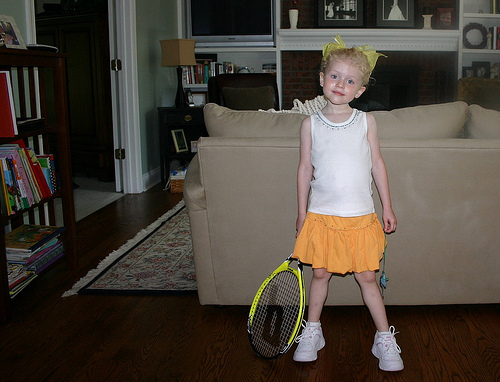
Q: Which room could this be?
A: It is a living room.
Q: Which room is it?
A: It is a living room.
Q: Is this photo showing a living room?
A: Yes, it is showing a living room.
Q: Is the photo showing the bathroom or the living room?
A: It is showing the living room.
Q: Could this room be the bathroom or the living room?
A: It is the living room.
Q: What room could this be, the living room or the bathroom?
A: It is the living room.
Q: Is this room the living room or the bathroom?
A: It is the living room.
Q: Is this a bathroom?
A: No, it is a living room.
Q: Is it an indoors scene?
A: Yes, it is indoors.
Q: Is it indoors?
A: Yes, it is indoors.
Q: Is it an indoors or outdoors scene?
A: It is indoors.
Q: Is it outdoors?
A: No, it is indoors.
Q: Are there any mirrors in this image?
A: No, there are no mirrors.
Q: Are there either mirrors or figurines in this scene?
A: No, there are no mirrors or figurines.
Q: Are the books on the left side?
A: Yes, the books are on the left of the image.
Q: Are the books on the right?
A: No, the books are on the left of the image.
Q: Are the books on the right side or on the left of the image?
A: The books are on the left of the image.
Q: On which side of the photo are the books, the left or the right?
A: The books are on the left of the image.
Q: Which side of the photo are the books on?
A: The books are on the left of the image.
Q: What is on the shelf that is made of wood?
A: The books are on the shelf.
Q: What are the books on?
A: The books are on the shelf.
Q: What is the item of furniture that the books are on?
A: The piece of furniture is a shelf.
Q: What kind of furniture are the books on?
A: The books are on the shelf.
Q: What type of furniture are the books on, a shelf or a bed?
A: The books are on a shelf.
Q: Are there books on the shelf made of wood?
A: Yes, there are books on the shelf.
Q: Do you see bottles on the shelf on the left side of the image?
A: No, there are books on the shelf.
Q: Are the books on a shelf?
A: Yes, the books are on a shelf.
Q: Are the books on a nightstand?
A: No, the books are on a shelf.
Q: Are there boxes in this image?
A: No, there are no boxes.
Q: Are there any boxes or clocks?
A: No, there are no boxes or clocks.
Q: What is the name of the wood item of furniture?
A: The piece of furniture is a shelf.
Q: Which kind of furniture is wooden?
A: The furniture is a shelf.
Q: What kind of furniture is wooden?
A: The furniture is a shelf.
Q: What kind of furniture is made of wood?
A: The furniture is a shelf.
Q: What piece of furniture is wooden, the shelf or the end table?
A: The shelf is wooden.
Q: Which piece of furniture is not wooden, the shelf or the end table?
A: The end table is not wooden.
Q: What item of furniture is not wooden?
A: The piece of furniture is an end table.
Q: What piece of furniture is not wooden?
A: The piece of furniture is an end table.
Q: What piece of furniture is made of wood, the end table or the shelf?
A: The shelf is made of wood.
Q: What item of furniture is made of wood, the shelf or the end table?
A: The shelf is made of wood.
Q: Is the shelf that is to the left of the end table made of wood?
A: Yes, the shelf is made of wood.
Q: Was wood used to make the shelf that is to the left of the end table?
A: Yes, the shelf is made of wood.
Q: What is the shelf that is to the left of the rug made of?
A: The shelf is made of wood.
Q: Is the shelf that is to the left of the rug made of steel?
A: No, the shelf is made of wood.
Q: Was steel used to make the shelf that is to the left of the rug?
A: No, the shelf is made of wood.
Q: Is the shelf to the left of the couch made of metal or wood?
A: The shelf is made of wood.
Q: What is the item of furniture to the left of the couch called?
A: The piece of furniture is a shelf.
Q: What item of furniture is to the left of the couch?
A: The piece of furniture is a shelf.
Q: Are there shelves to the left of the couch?
A: Yes, there is a shelf to the left of the couch.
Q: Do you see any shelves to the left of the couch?
A: Yes, there is a shelf to the left of the couch.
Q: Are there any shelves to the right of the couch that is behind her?
A: No, the shelf is to the left of the couch.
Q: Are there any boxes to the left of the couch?
A: No, there is a shelf to the left of the couch.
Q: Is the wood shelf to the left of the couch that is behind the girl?
A: Yes, the shelf is to the left of the couch.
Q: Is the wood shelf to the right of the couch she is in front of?
A: No, the shelf is to the left of the couch.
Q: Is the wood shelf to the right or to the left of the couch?
A: The shelf is to the left of the couch.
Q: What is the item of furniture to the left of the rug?
A: The piece of furniture is a shelf.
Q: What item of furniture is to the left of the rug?
A: The piece of furniture is a shelf.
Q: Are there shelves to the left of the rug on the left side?
A: Yes, there is a shelf to the left of the rug.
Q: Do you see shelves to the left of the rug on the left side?
A: Yes, there is a shelf to the left of the rug.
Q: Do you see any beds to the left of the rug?
A: No, there is a shelf to the left of the rug.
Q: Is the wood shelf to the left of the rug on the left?
A: Yes, the shelf is to the left of the rug.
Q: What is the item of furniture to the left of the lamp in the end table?
A: The piece of furniture is a shelf.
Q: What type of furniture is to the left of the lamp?
A: The piece of furniture is a shelf.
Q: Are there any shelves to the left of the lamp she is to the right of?
A: Yes, there is a shelf to the left of the lamp.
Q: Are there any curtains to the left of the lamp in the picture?
A: No, there is a shelf to the left of the lamp.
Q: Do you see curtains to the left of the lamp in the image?
A: No, there is a shelf to the left of the lamp.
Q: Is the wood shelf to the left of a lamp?
A: Yes, the shelf is to the left of a lamp.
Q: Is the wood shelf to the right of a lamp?
A: No, the shelf is to the left of a lamp.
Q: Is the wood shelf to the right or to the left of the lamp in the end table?
A: The shelf is to the left of the lamp.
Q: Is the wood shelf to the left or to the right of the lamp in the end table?
A: The shelf is to the left of the lamp.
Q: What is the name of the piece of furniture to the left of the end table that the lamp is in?
A: The piece of furniture is a shelf.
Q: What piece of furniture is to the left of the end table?
A: The piece of furniture is a shelf.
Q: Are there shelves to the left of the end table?
A: Yes, there is a shelf to the left of the end table.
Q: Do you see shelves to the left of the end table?
A: Yes, there is a shelf to the left of the end table.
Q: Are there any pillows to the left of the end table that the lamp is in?
A: No, there is a shelf to the left of the end table.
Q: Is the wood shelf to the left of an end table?
A: Yes, the shelf is to the left of an end table.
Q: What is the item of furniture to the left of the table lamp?
A: The piece of furniture is a shelf.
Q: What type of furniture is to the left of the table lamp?
A: The piece of furniture is a shelf.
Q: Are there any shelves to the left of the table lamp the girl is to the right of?
A: Yes, there is a shelf to the left of the table lamp.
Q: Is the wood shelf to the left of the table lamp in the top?
A: Yes, the shelf is to the left of the table lamp.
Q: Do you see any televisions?
A: Yes, there is a television.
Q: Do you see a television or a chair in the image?
A: Yes, there is a television.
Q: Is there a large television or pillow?
A: Yes, there is a large television.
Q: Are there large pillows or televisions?
A: Yes, there is a large television.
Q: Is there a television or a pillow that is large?
A: Yes, the television is large.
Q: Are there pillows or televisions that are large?
A: Yes, the television is large.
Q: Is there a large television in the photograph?
A: Yes, there is a large television.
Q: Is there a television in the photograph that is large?
A: Yes, there is a television that is large.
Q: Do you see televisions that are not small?
A: Yes, there is a large television.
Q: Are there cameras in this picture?
A: No, there are no cameras.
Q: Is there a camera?
A: No, there are no cameras.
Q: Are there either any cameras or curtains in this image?
A: No, there are no cameras or curtains.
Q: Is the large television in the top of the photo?
A: Yes, the TV is in the top of the image.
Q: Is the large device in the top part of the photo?
A: Yes, the TV is in the top of the image.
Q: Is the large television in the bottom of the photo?
A: No, the TV is in the top of the image.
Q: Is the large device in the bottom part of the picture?
A: No, the TV is in the top of the image.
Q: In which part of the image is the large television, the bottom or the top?
A: The TV is in the top of the image.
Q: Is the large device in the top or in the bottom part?
A: The TV is in the top of the image.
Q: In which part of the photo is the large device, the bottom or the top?
A: The TV is in the top of the image.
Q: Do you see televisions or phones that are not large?
A: No, there is a television but it is large.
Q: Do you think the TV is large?
A: Yes, the TV is large.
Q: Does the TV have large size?
A: Yes, the TV is large.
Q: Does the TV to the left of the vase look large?
A: Yes, the television is large.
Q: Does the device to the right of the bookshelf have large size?
A: Yes, the television is large.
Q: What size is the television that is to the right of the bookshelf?
A: The television is large.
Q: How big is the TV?
A: The TV is large.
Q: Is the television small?
A: No, the television is large.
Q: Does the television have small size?
A: No, the television is large.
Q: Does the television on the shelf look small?
A: No, the television is large.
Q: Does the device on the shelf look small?
A: No, the television is large.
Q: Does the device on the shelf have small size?
A: No, the television is large.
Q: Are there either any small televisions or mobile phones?
A: No, there is a television but it is large.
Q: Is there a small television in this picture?
A: No, there is a television but it is large.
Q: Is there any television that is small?
A: No, there is a television but it is large.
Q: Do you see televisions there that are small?
A: No, there is a television but it is large.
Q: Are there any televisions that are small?
A: No, there is a television but it is large.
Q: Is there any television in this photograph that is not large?
A: No, there is a television but it is large.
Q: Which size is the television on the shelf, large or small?
A: The television is large.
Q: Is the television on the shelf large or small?
A: The television is large.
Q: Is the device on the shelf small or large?
A: The television is large.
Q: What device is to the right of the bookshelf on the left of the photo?
A: The device is a television.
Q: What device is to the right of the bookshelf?
A: The device is a television.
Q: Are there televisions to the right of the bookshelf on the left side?
A: Yes, there is a television to the right of the bookshelf.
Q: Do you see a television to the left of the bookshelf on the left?
A: No, the television is to the right of the bookshelf.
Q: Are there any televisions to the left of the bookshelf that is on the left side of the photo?
A: No, the television is to the right of the bookshelf.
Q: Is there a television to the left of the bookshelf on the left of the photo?
A: No, the television is to the right of the bookshelf.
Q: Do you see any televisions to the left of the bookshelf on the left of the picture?
A: No, the television is to the right of the bookshelf.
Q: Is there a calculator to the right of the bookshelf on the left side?
A: No, there is a television to the right of the bookshelf.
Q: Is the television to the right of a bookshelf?
A: Yes, the television is to the right of a bookshelf.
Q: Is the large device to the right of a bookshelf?
A: Yes, the television is to the right of a bookshelf.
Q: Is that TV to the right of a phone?
A: No, the TV is to the right of a bookshelf.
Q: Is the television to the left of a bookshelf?
A: No, the television is to the right of a bookshelf.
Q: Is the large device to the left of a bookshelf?
A: No, the television is to the right of a bookshelf.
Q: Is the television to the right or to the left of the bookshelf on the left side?
A: The television is to the right of the bookshelf.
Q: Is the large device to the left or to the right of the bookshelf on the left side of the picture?
A: The television is to the right of the bookshelf.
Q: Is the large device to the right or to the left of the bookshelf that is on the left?
A: The television is to the right of the bookshelf.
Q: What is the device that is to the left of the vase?
A: The device is a television.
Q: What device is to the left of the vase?
A: The device is a television.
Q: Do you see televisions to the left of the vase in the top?
A: Yes, there is a television to the left of the vase.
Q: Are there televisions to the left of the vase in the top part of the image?
A: Yes, there is a television to the left of the vase.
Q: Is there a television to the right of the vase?
A: No, the television is to the left of the vase.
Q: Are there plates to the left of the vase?
A: No, there is a television to the left of the vase.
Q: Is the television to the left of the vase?
A: Yes, the television is to the left of the vase.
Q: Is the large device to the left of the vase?
A: Yes, the television is to the left of the vase.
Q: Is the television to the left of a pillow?
A: No, the television is to the left of the vase.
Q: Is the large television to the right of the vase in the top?
A: No, the television is to the left of the vase.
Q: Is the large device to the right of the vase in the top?
A: No, the television is to the left of the vase.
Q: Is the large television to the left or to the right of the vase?
A: The television is to the left of the vase.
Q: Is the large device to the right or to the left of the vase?
A: The television is to the left of the vase.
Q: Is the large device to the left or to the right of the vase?
A: The television is to the left of the vase.